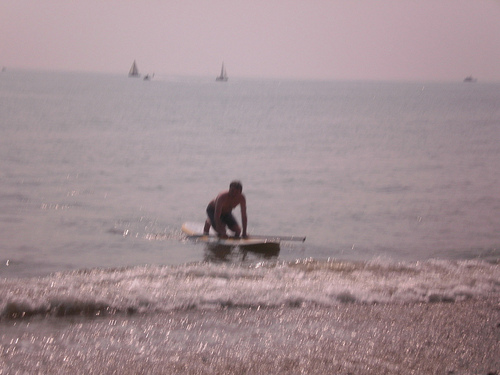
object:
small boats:
[142, 72, 154, 83]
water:
[1, 77, 498, 319]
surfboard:
[182, 217, 283, 249]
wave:
[0, 260, 498, 318]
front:
[236, 235, 288, 252]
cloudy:
[0, 0, 500, 79]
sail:
[128, 57, 141, 75]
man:
[201, 178, 249, 240]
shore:
[0, 305, 500, 374]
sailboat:
[126, 60, 145, 79]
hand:
[239, 231, 248, 241]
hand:
[218, 232, 226, 241]